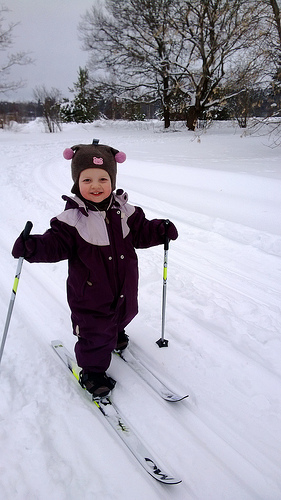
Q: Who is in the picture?
A: A young girl.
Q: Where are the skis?
A: On the girl's feet.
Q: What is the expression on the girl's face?
A: Happy.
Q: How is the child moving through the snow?
A: On skis.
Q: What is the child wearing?
A: A purple jumpsuit.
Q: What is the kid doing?
A: Skiing.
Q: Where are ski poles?
A: In kid's hands.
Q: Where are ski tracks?
A: On the snow.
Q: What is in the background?
A: Trees.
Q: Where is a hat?
A: On kid's head.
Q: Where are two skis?
A: Under the kid's feet.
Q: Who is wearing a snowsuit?
A: The child.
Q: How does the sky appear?
A: Overcast.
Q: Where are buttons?
A: On the snowsuit.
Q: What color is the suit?
A: Brown.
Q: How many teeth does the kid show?
A: Two.